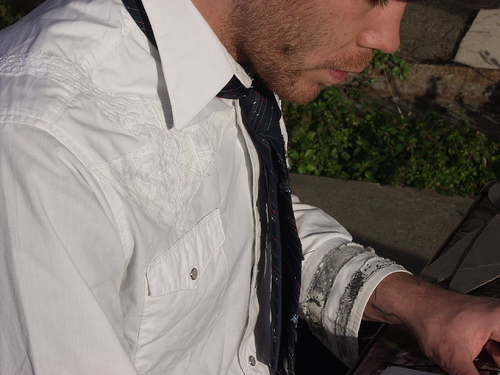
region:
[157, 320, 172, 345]
the pocket is white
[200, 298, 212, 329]
the pocket is white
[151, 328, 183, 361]
the pocket is white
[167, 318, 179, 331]
the pocket is white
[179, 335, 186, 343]
the pocket is white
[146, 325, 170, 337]
the pocket is white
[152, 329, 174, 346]
the pocket is white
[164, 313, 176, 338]
the pocket is white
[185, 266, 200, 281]
silver button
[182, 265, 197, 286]
silver button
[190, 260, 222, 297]
silver button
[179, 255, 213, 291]
silver button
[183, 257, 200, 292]
silver button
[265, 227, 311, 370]
A black tie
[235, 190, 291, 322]
A black tie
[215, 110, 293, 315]
A black tie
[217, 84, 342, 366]
A black tie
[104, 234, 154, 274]
a man in white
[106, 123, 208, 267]
a man in white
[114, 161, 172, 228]
a man in white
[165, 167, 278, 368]
a man in white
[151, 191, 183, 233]
a man in white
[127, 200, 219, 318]
a man in white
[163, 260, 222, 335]
a man in white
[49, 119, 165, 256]
a man in white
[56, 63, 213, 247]
a man in white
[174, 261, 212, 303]
silver button on shirt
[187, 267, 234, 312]
silver button on shirt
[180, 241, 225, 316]
silver button on shirt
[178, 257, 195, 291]
silver button on shirt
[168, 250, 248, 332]
silver button on shirt